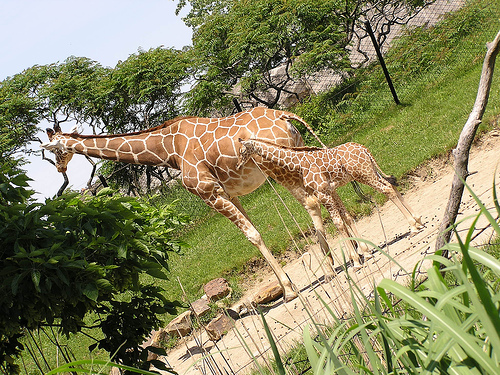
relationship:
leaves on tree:
[55, 232, 163, 295] [0, 152, 189, 372]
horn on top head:
[44, 121, 61, 137] [40, 124, 72, 170]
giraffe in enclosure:
[39, 107, 370, 303] [4, 0, 497, 370]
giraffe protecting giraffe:
[42, 107, 373, 301] [234, 136, 422, 273]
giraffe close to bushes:
[39, 107, 370, 303] [0, 167, 497, 372]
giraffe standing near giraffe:
[236, 136, 425, 273] [42, 107, 373, 301]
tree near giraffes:
[2, 127, 200, 370] [35, 94, 431, 310]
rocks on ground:
[146, 271, 266, 345] [147, 214, 424, 371]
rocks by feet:
[206, 278, 278, 333] [276, 273, 336, 289]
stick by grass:
[435, 33, 496, 263] [319, 254, 496, 370]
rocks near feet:
[177, 279, 277, 331] [274, 217, 416, 272]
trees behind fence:
[3, 0, 350, 129] [101, 5, 484, 130]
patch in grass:
[176, 154, 496, 328] [209, 10, 491, 143]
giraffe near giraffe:
[234, 136, 422, 273] [39, 107, 370, 303]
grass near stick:
[304, 258, 495, 349] [438, 29, 495, 245]